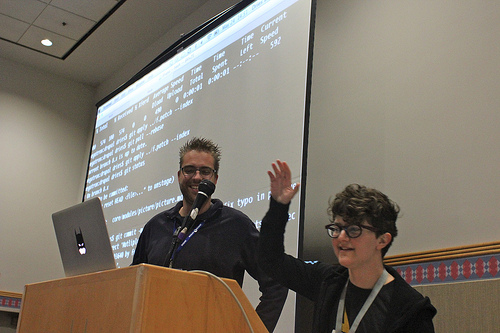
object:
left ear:
[377, 232, 392, 249]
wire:
[185, 271, 257, 333]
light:
[40, 38, 53, 46]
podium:
[15, 264, 275, 333]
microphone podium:
[162, 178, 217, 268]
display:
[83, 0, 321, 331]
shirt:
[131, 197, 287, 332]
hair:
[327, 183, 401, 258]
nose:
[337, 234, 350, 242]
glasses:
[180, 165, 217, 176]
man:
[129, 137, 289, 333]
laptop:
[50, 196, 117, 277]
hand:
[267, 159, 300, 205]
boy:
[256, 160, 439, 333]